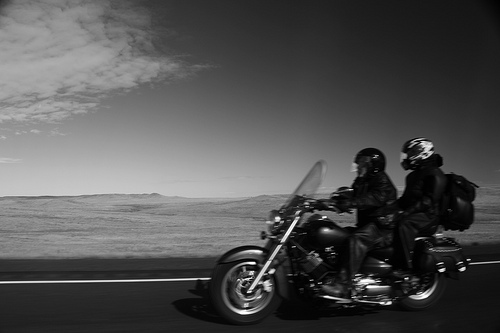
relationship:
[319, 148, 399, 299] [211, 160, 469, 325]
driver riding bike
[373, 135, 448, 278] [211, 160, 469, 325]
passenger riding bike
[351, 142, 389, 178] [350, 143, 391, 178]
helmet on head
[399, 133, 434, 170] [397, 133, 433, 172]
helmet on head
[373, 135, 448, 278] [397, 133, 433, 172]
passenger has head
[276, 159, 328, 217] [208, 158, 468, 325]
windshield front of bike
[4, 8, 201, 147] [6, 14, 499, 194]
cloud in sky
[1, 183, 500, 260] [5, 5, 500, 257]
plains in background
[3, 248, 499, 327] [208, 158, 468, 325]
pavement under bike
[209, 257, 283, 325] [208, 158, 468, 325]
front wheel on bike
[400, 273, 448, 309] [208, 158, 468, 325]
back wheel on bike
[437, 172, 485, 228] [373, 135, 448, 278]
backpack on passenger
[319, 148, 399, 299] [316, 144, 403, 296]
driver on motorbike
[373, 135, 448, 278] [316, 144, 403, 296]
passenger on motorbike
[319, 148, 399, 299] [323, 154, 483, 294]
driver wearing black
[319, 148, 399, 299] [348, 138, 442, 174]
driver wearing helmets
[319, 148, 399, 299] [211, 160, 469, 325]
driver on bike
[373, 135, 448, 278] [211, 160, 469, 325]
passenger on bike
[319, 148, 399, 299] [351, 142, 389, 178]
driver with helmet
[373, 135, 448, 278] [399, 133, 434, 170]
passenger wearing helmet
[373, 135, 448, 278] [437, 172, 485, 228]
passenger wearing backpack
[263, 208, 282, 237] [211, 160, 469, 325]
headlight on bike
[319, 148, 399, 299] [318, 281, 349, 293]
driver wearing boots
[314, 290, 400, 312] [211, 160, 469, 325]
pipe on bike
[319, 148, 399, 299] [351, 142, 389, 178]
driver wearing helmet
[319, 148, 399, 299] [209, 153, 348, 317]
driver in front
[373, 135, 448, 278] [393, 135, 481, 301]
passenger in back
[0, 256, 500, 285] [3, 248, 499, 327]
line on pavement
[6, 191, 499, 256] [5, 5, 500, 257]
mountain in background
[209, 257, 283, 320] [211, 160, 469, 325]
front wheel on bike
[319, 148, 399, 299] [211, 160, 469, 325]
driver driving bike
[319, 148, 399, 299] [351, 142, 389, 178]
driver in helmet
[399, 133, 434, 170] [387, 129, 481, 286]
helmet on passenger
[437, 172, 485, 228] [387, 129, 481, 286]
backpack on passenger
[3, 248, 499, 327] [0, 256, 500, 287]
pavement with line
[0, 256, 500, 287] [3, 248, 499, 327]
line down pavement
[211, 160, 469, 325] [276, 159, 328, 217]
bike with windshield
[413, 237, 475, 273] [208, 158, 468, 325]
saddle bag on bike